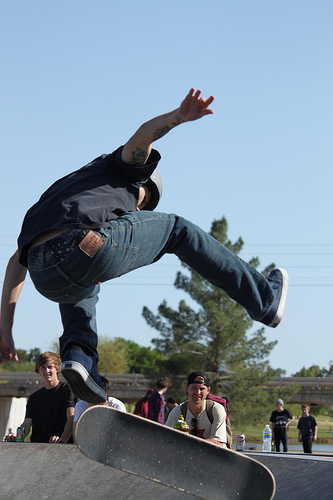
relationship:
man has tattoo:
[20, 126, 291, 383] [129, 147, 148, 165]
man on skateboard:
[20, 126, 291, 383] [78, 406, 259, 498]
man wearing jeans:
[20, 126, 291, 383] [27, 210, 275, 362]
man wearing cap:
[20, 126, 291, 383] [148, 176, 169, 193]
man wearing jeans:
[20, 126, 291, 383] [124, 221, 234, 272]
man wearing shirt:
[20, 126, 291, 383] [76, 166, 129, 215]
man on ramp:
[20, 126, 291, 383] [21, 449, 74, 490]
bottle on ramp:
[256, 423, 279, 453] [21, 449, 74, 490]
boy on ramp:
[184, 369, 224, 427] [21, 449, 74, 490]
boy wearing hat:
[184, 369, 224, 427] [186, 366, 213, 391]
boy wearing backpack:
[184, 369, 224, 427] [209, 392, 242, 408]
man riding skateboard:
[20, 126, 291, 383] [78, 406, 259, 498]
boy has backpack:
[184, 369, 224, 427] [209, 392, 242, 408]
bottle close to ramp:
[256, 423, 279, 453] [21, 449, 74, 490]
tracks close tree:
[284, 375, 317, 402] [173, 294, 244, 370]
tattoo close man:
[129, 147, 148, 165] [20, 126, 291, 383]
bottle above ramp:
[256, 423, 279, 453] [21, 449, 74, 490]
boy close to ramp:
[184, 369, 224, 427] [21, 449, 74, 490]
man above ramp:
[20, 126, 291, 383] [21, 449, 74, 490]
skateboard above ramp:
[78, 406, 259, 498] [21, 449, 74, 490]